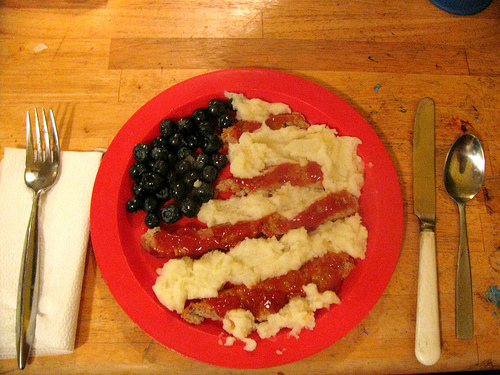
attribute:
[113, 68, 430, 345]
plate — Round 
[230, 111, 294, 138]
ketchup — red 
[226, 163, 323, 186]
ketchup — red 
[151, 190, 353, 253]
ketchup — red 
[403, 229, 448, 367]
handle — white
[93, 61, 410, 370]
plate — Red 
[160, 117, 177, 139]
berrie — blue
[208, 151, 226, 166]
berrie — blue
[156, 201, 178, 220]
berrie — blue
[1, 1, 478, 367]
surface — wood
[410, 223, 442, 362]
handle — white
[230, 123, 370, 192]
potatoe — mashed , white